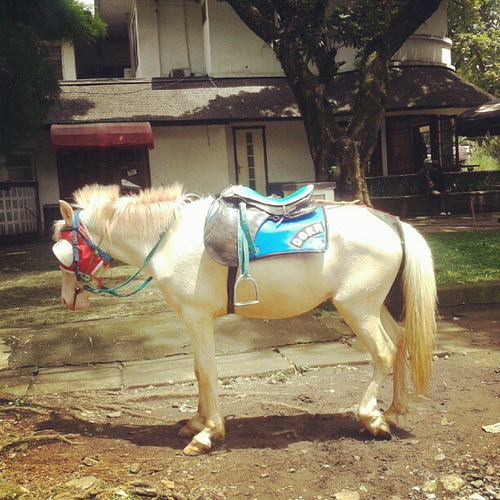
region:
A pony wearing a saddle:
[51, 183, 438, 456]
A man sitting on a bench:
[413, 157, 458, 224]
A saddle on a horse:
[203, 182, 329, 307]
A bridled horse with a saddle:
[51, 182, 438, 457]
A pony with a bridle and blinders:
[49, 183, 183, 313]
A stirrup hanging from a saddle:
[232, 257, 262, 306]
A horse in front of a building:
[52, 64, 436, 455]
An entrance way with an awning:
[48, 123, 156, 183]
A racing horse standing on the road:
[49, 178, 436, 455]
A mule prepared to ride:
[52, 182, 439, 453]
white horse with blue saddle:
[37, 173, 437, 458]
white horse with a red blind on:
[41, 171, 443, 458]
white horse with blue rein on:
[41, 160, 443, 456]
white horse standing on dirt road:
[31, 170, 439, 464]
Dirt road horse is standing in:
[0, 348, 499, 499]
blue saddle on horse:
[222, 173, 317, 220]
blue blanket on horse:
[201, 180, 329, 266]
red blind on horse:
[50, 229, 115, 288]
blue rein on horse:
[67, 193, 187, 299]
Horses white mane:
[43, 175, 183, 241]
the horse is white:
[26, 165, 438, 377]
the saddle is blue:
[198, 179, 335, 274]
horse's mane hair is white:
[73, 186, 195, 231]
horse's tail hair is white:
[385, 225, 472, 401]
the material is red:
[55, 219, 123, 281]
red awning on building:
[46, 111, 184, 162]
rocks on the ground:
[404, 443, 473, 493]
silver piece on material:
[219, 263, 273, 315]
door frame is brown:
[226, 113, 273, 196]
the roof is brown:
[93, 72, 478, 129]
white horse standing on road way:
[42, 172, 438, 441]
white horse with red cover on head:
[26, 178, 429, 444]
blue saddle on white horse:
[207, 170, 323, 267]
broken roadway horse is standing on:
[11, 368, 499, 499]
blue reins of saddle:
[65, 189, 182, 294]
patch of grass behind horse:
[395, 220, 499, 282]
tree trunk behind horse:
[244, 4, 431, 190]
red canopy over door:
[43, 113, 157, 148]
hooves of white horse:
[166, 419, 396, 456]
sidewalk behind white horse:
[11, 307, 488, 385]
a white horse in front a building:
[34, 176, 466, 459]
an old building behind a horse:
[7, 5, 496, 297]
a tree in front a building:
[226, 2, 433, 202]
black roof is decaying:
[46, 63, 498, 123]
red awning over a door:
[45, 116, 159, 154]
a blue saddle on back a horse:
[47, 163, 445, 458]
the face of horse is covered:
[44, 196, 116, 320]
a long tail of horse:
[396, 217, 445, 393]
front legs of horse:
[174, 318, 237, 465]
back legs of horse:
[343, 310, 425, 441]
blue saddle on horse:
[213, 180, 344, 265]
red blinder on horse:
[41, 209, 108, 282]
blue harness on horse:
[66, 208, 183, 302]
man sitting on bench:
[413, 154, 451, 224]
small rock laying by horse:
[127, 457, 147, 474]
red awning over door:
[45, 119, 163, 154]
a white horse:
[46, 180, 433, 454]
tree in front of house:
[223, 6, 447, 218]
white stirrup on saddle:
[231, 270, 271, 320]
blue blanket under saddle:
[248, 203, 339, 256]